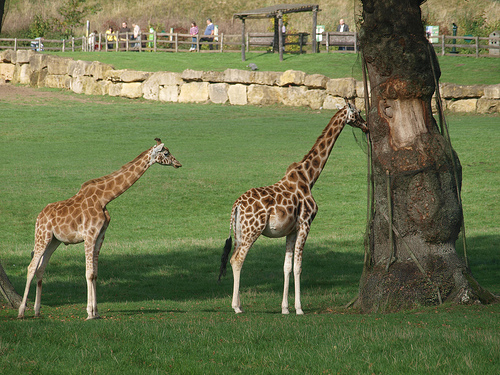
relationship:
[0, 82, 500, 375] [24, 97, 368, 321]
enclosure with giraffes